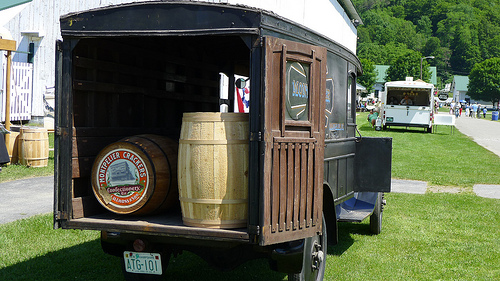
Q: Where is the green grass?
A: On the ground.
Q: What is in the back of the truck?
A: Wooden barrels.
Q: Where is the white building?
A: To the left of the truck.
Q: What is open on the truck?
A: The back doors.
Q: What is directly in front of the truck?
A: A sidewalk.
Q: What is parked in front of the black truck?
A: A white truck.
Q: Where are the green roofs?
A: On two white buildings down the street.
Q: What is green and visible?
A: Grass.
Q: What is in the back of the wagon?
A: Barrels.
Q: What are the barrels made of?
A: Wood.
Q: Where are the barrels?
A: Truck.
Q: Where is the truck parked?
A: Grass.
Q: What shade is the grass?
A: Green.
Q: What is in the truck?
A: Barrels.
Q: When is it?
A: Day time.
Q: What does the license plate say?
A: ATG-101.